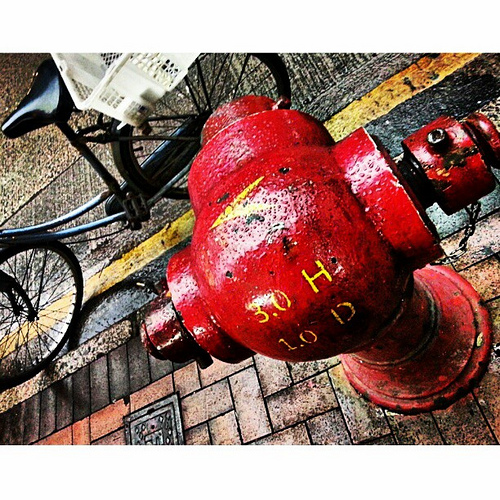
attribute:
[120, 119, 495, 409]
hydrant — red, wet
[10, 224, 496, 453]
sidewalk — brick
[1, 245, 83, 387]
wheel — tire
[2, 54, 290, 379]
bicycle — black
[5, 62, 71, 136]
seat — black, leather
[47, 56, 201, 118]
basket — plastic, white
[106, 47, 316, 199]
wheel — back, tire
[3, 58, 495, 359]
road — gray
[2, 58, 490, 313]
line — yellow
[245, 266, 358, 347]
numbers — yellow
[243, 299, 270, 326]
3 — number, yellow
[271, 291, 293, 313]
0 — number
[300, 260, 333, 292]
h — letter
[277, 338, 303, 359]
l — letter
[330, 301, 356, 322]
d — letter